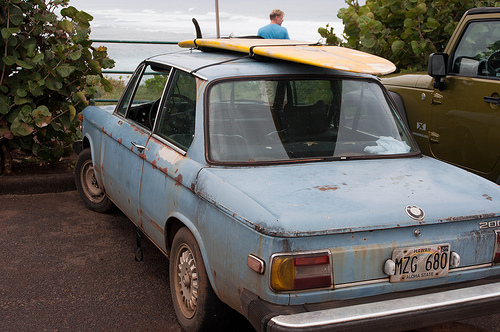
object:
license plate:
[385, 241, 452, 285]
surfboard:
[175, 30, 398, 77]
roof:
[141, 42, 379, 82]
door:
[94, 63, 172, 229]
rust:
[116, 137, 124, 147]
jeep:
[381, 5, 500, 179]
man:
[252, 7, 296, 44]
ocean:
[0, 0, 365, 86]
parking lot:
[34, 228, 97, 289]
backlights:
[267, 250, 340, 297]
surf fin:
[187, 16, 207, 42]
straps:
[185, 42, 346, 74]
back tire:
[159, 222, 217, 331]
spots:
[149, 158, 159, 170]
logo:
[401, 201, 430, 222]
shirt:
[253, 23, 293, 40]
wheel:
[149, 92, 198, 133]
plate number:
[394, 251, 448, 277]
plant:
[0, 0, 142, 177]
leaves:
[66, 12, 93, 29]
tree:
[370, 19, 396, 36]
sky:
[139, 6, 214, 23]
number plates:
[473, 220, 499, 232]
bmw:
[68, 44, 499, 332]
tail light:
[491, 228, 500, 267]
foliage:
[16, 108, 36, 125]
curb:
[0, 171, 75, 194]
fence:
[0, 35, 397, 140]